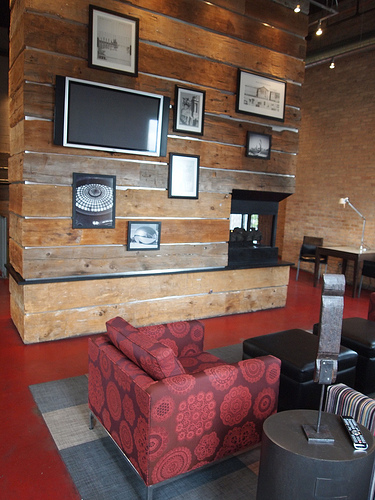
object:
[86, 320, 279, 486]
chair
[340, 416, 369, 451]
remote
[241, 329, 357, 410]
ottoman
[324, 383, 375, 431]
sofa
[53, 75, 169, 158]
tv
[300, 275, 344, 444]
lamp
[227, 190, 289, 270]
fireplace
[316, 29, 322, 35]
light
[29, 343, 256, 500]
carpet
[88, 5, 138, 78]
photo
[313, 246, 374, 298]
table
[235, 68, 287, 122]
picture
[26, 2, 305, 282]
wall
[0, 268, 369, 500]
floor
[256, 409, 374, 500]
table